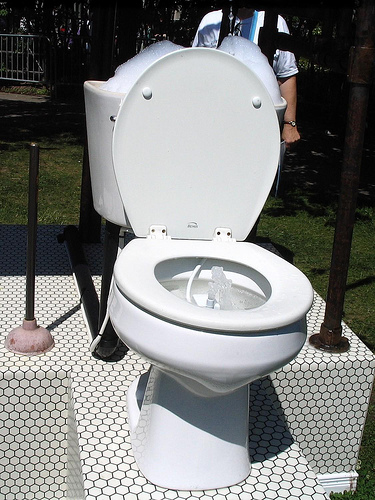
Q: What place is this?
A: It is a display.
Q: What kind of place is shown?
A: It is a display.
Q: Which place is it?
A: It is a display.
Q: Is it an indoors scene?
A: Yes, it is indoors.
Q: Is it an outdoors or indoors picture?
A: It is indoors.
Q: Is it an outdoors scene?
A: No, it is indoors.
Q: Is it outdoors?
A: No, it is indoors.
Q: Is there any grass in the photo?
A: Yes, there is grass.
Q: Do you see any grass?
A: Yes, there is grass.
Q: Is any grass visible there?
A: Yes, there is grass.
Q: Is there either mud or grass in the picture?
A: Yes, there is grass.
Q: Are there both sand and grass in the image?
A: No, there is grass but no sand.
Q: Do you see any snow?
A: No, there is no snow.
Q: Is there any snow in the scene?
A: No, there is no snow.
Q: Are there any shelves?
A: No, there are no shelves.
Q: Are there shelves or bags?
A: No, there are no shelves or bags.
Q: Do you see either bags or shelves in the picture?
A: No, there are no shelves or bags.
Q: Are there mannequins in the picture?
A: No, there are no mannequins.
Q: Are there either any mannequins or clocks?
A: No, there are no mannequins or clocks.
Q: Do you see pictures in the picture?
A: No, there are no pictures.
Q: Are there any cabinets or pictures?
A: No, there are no pictures or cabinets.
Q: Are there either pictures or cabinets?
A: No, there are no pictures or cabinets.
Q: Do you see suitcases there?
A: No, there are no suitcases.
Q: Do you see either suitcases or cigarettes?
A: No, there are no suitcases or cigarettes.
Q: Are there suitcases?
A: No, there are no suitcases.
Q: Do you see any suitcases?
A: No, there are no suitcases.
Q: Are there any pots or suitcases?
A: No, there are no suitcases or pots.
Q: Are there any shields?
A: No, there are no shields.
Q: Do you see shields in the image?
A: No, there are no shields.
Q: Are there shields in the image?
A: No, there are no shields.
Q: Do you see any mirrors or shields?
A: No, there are no shields or mirrors.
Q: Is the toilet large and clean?
A: Yes, the toilet is large and clean.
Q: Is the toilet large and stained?
A: No, the toilet is large but clean.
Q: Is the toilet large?
A: Yes, the toilet is large.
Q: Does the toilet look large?
A: Yes, the toilet is large.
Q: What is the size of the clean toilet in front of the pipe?
A: The toilet is large.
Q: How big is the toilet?
A: The toilet is large.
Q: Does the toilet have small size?
A: No, the toilet is large.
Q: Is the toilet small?
A: No, the toilet is large.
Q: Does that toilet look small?
A: No, the toilet is large.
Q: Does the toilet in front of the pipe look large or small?
A: The toilet is large.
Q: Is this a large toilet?
A: Yes, this is a large toilet.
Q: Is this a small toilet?
A: No, this is a large toilet.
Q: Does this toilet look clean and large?
A: Yes, the toilet is clean and large.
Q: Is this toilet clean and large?
A: Yes, the toilet is clean and large.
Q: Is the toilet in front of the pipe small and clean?
A: No, the toilet is clean but large.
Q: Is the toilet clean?
A: Yes, the toilet is clean.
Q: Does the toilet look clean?
A: Yes, the toilet is clean.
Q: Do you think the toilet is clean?
A: Yes, the toilet is clean.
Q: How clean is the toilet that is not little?
A: The toilet is clean.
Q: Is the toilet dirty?
A: No, the toilet is clean.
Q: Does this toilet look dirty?
A: No, the toilet is clean.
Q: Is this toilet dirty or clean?
A: The toilet is clean.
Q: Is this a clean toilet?
A: Yes, this is a clean toilet.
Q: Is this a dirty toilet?
A: No, this is a clean toilet.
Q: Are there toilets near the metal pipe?
A: Yes, there is a toilet near the pipe.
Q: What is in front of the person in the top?
A: The toilet is in front of the person.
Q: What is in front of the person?
A: The toilet is in front of the person.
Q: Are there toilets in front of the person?
A: Yes, there is a toilet in front of the person.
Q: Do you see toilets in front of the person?
A: Yes, there is a toilet in front of the person.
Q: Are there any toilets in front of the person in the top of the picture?
A: Yes, there is a toilet in front of the person.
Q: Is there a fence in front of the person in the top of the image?
A: No, there is a toilet in front of the person.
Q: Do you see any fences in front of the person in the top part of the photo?
A: No, there is a toilet in front of the person.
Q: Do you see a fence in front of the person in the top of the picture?
A: No, there is a toilet in front of the person.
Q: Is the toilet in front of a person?
A: Yes, the toilet is in front of a person.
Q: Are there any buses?
A: No, there are no buses.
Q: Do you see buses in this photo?
A: No, there are no buses.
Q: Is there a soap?
A: Yes, there is a soap.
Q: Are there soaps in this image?
A: Yes, there is a soap.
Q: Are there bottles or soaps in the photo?
A: Yes, there is a soap.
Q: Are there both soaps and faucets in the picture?
A: No, there is a soap but no faucets.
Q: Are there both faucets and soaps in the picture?
A: No, there is a soap but no faucets.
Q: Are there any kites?
A: No, there are no kites.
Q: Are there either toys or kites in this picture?
A: No, there are no kites or toys.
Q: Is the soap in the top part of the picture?
A: Yes, the soap is in the top of the image.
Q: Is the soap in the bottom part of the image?
A: No, the soap is in the top of the image.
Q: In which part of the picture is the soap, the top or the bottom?
A: The soap is in the top of the image.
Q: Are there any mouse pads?
A: No, there are no mouse pads.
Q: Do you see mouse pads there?
A: No, there are no mouse pads.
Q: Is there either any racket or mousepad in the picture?
A: No, there are no mouse pads or rackets.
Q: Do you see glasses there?
A: No, there are no glasses.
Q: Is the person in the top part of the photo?
A: Yes, the person is in the top of the image.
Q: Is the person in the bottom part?
A: No, the person is in the top of the image.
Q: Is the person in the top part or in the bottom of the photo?
A: The person is in the top of the image.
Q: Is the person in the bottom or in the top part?
A: The person is in the top of the image.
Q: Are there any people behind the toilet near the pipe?
A: Yes, there is a person behind the toilet.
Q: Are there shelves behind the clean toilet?
A: No, there is a person behind the toilet.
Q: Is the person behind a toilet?
A: Yes, the person is behind a toilet.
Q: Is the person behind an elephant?
A: No, the person is behind a toilet.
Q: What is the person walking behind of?
A: The person is walking behind the toilet.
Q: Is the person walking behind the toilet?
A: Yes, the person is walking behind the toilet.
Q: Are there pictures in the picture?
A: No, there are no pictures.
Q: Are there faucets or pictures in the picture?
A: No, there are no pictures or faucets.